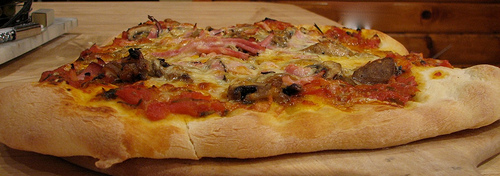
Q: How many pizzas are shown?
A: Two pizzas.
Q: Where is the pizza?
A: On top of the table.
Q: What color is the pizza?
A: Red, brown, and yellow.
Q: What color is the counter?
A: Light brown.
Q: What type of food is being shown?
A: A pizza.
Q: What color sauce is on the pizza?
A: Red.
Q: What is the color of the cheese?
A: Yellow.